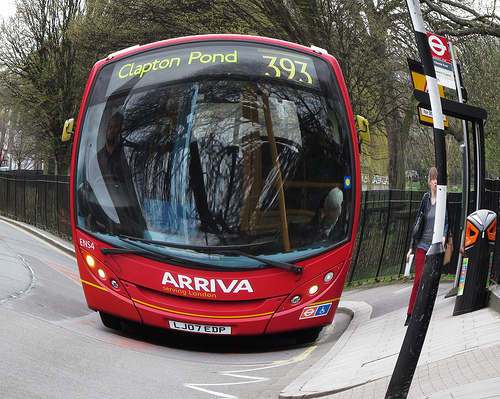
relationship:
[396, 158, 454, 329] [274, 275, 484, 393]
woman on sidewalk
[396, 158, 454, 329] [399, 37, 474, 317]
woman at bus stop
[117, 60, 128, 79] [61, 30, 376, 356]
letter on bus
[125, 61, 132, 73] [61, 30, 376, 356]
letter on bus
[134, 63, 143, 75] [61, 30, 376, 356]
letter on bus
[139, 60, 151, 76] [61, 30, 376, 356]
letter on bus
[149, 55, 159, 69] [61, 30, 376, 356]
letter on bus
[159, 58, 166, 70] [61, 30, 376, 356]
letter on bus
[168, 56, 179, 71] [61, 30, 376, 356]
letter on bus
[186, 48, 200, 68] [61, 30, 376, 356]
letter on bus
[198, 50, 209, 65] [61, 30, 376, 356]
letter on bus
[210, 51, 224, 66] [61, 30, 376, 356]
letter on bus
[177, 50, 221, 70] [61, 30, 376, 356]
letter on bus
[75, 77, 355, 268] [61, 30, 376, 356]
windshield of bus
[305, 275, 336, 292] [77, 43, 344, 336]
head light right side front of bus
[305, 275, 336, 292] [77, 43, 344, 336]
head light left side front of bus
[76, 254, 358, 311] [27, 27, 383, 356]
head lights left side front of bus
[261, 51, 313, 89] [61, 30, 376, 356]
number on bus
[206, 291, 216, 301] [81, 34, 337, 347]
letter on bus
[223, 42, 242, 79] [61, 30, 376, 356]
letter on bus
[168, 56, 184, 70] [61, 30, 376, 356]
letter on bus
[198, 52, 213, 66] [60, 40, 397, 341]
letter on bus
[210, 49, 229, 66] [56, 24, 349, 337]
letter on bus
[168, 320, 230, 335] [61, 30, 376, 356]
license plate of bus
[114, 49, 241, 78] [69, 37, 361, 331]
destination name on bus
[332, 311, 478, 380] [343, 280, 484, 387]
concrete on sidewalk